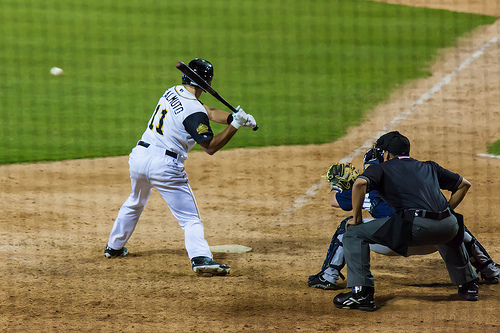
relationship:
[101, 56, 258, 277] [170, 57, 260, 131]
athlete holding bat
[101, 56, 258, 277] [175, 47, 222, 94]
athlete has helmet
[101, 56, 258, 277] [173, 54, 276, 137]
athlete holds bat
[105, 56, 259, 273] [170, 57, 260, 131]
athlete swing bat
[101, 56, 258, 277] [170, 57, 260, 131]
athlete swing bat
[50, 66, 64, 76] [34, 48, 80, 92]
ball in air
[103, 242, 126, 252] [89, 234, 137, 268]
foot in shoe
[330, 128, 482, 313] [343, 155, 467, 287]
catcher dress dark blue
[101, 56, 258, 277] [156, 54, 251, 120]
athlete prepares bat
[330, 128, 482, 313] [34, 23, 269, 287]
catcher judge pitch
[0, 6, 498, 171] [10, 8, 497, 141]
grass on infield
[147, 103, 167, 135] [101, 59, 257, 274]
number on player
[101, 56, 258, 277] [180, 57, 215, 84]
athlete wears helmet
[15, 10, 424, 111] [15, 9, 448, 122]
grass on infield grass